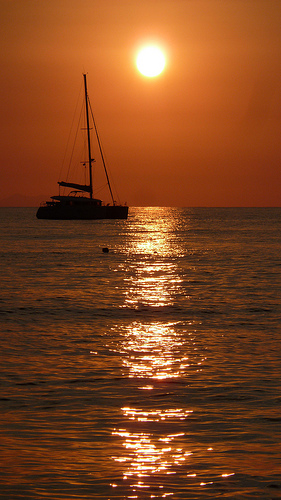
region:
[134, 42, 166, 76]
yellow son in sky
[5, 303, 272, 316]
wave formed in ocean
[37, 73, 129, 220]
boat sailing in water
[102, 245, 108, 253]
bouy floating in water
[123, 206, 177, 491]
sun reflection in water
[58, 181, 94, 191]
sun canopy on boat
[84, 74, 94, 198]
wood mast on boat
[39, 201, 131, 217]
boat sitting in ocean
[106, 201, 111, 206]
person standing on boat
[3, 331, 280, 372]
ripples in ocean water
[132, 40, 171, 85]
The sun above the water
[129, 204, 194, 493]
The sun reflected on the water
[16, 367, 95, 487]
The water is calm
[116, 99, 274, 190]
The orange sky above the boat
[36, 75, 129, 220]
A boat on the water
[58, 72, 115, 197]
The sails on the boat are not up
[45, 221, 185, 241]
Water by the boat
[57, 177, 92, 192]
The sails on the boat are down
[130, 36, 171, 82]
The sun is far above the boat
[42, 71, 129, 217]
A boat is sitting on the calm water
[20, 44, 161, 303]
A sailboat is on the water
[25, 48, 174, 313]
A sailboat is in the ocean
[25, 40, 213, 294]
A sailboat is carrying people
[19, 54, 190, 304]
A sailboat is coming into a marina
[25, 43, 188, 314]
A boat is on a cruise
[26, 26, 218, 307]
The boat is under the setting sun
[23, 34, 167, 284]
A sailboat has its sails down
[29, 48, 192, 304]
The sailboat has a tall mast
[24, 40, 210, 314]
The sailboat is out fishing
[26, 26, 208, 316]
The boat is traveling over the sea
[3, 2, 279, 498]
picture of sunset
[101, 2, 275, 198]
the sun on an orange sky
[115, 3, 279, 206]
a yellow sun on an orange sky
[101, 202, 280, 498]
reflection of sun on the water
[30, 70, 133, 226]
a boat in the ocean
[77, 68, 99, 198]
mast of boat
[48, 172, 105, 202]
sail of boat near mast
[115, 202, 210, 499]
a reflection on sea water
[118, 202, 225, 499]
light reflected on the water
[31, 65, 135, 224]
mast of boat is high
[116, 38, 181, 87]
sun in the sky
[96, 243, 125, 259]
object floating in the water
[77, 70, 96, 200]
long mast of boat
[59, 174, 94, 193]
rolled up sail of boat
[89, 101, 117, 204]
ropes hanging down from mast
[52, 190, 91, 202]
covering on top of boat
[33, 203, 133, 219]
body of boat on water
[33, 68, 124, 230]
sail boat on the water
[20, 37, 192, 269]
sail boat with sun in background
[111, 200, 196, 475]
line of sunlight on illuminating ocean